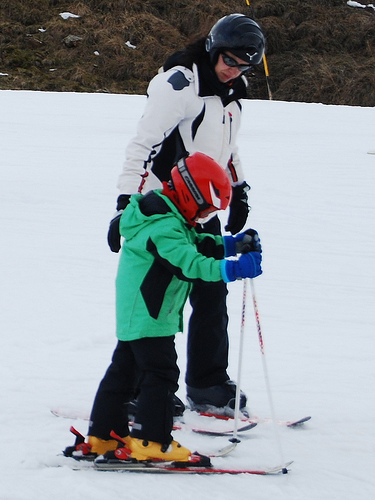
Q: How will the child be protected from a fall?
A: Helmet.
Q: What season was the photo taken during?
A: Winter.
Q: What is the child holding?
A: Ski poles.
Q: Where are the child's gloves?
A: Hands.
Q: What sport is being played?
A: Skiing.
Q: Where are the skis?
A: The feet.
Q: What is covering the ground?
A: Snow.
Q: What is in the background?
A: Trees.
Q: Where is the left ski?
A: On the left foot.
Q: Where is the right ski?
A: On the right foot.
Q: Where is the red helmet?
A: On the boy.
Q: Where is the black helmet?
A: On the woman.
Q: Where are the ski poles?
A: In the hands.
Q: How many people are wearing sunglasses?
A: One.